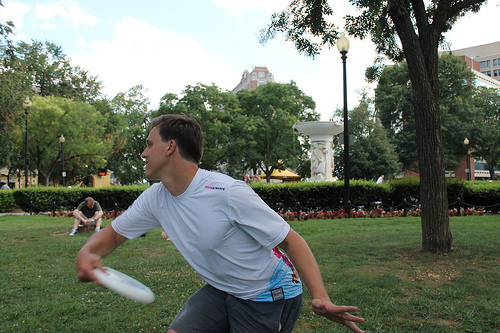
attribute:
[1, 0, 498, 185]
leaf — green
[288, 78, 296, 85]
leaf — green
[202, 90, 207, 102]
leaf — green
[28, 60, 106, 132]
leaf — green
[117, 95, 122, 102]
leaf — green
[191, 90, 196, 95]
leaf — green